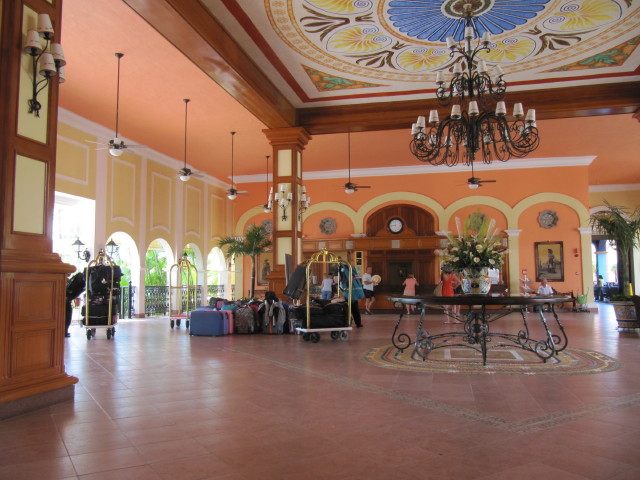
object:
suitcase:
[234, 302, 257, 335]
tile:
[432, 379, 476, 410]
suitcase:
[190, 310, 229, 337]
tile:
[377, 378, 403, 407]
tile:
[543, 383, 566, 397]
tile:
[339, 349, 359, 367]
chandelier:
[408, 0, 541, 168]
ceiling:
[203, 0, 638, 112]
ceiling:
[58, 0, 273, 181]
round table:
[384, 294, 572, 366]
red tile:
[249, 384, 351, 480]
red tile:
[54, 410, 214, 480]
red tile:
[113, 330, 171, 372]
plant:
[433, 205, 512, 294]